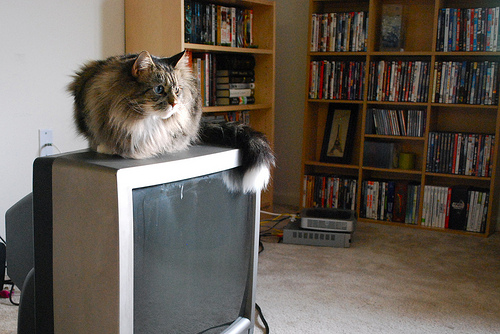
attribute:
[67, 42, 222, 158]
cat — fluffy, furry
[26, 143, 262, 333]
television — silver, turned off, traditional, large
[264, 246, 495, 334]
carpet — cream, beige, light brown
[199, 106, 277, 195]
tail — fluffy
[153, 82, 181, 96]
eyes — blue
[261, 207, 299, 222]
cable — white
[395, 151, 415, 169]
cup — green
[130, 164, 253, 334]
screen — dirty, gray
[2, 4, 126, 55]
wall — white, light gray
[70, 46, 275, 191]
fur — long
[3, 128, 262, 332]
tv set — thick